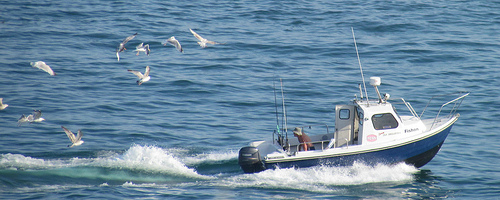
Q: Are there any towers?
A: No, there are no towers.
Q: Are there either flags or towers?
A: No, there are no towers or flags.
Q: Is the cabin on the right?
A: Yes, the cabin is on the right of the image.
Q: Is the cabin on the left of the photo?
A: No, the cabin is on the right of the image.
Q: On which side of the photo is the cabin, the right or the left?
A: The cabin is on the right of the image.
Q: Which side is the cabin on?
A: The cabin is on the right of the image.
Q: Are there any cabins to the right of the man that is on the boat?
A: Yes, there is a cabin to the right of the man.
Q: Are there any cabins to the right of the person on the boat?
A: Yes, there is a cabin to the right of the man.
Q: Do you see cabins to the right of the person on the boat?
A: Yes, there is a cabin to the right of the man.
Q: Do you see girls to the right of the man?
A: No, there is a cabin to the right of the man.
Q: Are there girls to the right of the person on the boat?
A: No, there is a cabin to the right of the man.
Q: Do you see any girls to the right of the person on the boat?
A: No, there is a cabin to the right of the man.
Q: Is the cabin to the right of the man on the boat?
A: Yes, the cabin is to the right of the man.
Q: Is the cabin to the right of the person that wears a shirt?
A: Yes, the cabin is to the right of the man.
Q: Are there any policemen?
A: No, there are no policemen.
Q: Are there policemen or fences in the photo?
A: No, there are no policemen or fences.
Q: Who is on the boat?
A: The man is on the boat.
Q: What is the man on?
A: The man is on the boat.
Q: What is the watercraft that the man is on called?
A: The watercraft is a boat.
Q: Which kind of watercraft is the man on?
A: The man is on the boat.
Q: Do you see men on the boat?
A: Yes, there is a man on the boat.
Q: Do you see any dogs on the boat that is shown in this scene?
A: No, there is a man on the boat.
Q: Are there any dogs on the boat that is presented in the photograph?
A: No, there is a man on the boat.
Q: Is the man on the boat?
A: Yes, the man is on the boat.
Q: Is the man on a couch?
A: No, the man is on the boat.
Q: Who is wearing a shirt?
A: The man is wearing a shirt.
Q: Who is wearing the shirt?
A: The man is wearing a shirt.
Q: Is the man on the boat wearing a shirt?
A: Yes, the man is wearing a shirt.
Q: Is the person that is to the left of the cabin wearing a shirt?
A: Yes, the man is wearing a shirt.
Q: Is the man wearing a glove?
A: No, the man is wearing a shirt.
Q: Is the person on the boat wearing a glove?
A: No, the man is wearing a shirt.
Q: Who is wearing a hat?
A: The man is wearing a hat.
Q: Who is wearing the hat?
A: The man is wearing a hat.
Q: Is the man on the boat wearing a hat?
A: Yes, the man is wearing a hat.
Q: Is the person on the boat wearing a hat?
A: Yes, the man is wearing a hat.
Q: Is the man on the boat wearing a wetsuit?
A: No, the man is wearing a hat.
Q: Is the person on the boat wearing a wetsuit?
A: No, the man is wearing a hat.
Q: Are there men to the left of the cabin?
A: Yes, there is a man to the left of the cabin.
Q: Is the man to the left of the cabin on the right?
A: Yes, the man is to the left of the cabin.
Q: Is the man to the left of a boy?
A: No, the man is to the left of the cabin.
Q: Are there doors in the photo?
A: Yes, there is a door.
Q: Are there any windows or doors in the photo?
A: Yes, there is a door.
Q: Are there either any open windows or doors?
A: Yes, there is an open door.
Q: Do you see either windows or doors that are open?
A: Yes, the door is open.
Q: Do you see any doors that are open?
A: Yes, there is an open door.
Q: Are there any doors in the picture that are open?
A: Yes, there is a door that is open.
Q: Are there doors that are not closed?
A: Yes, there is a open door.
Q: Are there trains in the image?
A: No, there are no trains.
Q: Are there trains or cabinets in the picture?
A: No, there are no trains or cabinets.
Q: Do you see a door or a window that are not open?
A: No, there is a door but it is open.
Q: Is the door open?
A: Yes, the door is open.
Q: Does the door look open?
A: Yes, the door is open.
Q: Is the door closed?
A: No, the door is open.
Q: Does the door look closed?
A: No, the door is open.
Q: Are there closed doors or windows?
A: No, there is a door but it is open.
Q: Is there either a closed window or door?
A: No, there is a door but it is open.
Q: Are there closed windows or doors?
A: No, there is a door but it is open.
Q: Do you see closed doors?
A: No, there is a door but it is open.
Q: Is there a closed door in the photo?
A: No, there is a door but it is open.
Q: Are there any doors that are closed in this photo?
A: No, there is a door but it is open.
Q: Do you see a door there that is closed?
A: No, there is a door but it is open.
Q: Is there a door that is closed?
A: No, there is a door but it is open.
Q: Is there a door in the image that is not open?
A: No, there is a door but it is open.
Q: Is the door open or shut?
A: The door is open.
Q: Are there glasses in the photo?
A: No, there are no glasses.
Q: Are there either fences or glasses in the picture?
A: No, there are no glasses or fences.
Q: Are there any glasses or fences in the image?
A: No, there are no glasses or fences.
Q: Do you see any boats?
A: Yes, there is a boat.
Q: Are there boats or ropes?
A: Yes, there is a boat.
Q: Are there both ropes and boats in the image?
A: No, there is a boat but no ropes.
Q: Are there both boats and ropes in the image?
A: No, there is a boat but no ropes.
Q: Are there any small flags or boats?
A: Yes, there is a small boat.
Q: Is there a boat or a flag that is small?
A: Yes, the boat is small.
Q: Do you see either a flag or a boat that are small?
A: Yes, the boat is small.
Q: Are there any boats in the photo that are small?
A: Yes, there is a small boat.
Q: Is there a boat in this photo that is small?
A: Yes, there is a small boat.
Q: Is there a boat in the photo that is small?
A: Yes, there is a boat that is small.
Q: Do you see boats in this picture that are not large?
A: Yes, there is a small boat.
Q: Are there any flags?
A: No, there are no flags.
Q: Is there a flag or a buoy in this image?
A: No, there are no flags or buoys.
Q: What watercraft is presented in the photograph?
A: The watercraft is a boat.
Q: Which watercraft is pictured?
A: The watercraft is a boat.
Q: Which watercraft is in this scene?
A: The watercraft is a boat.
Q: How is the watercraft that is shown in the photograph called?
A: The watercraft is a boat.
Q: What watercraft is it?
A: The watercraft is a boat.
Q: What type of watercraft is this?
A: This is a boat.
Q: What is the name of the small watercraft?
A: The watercraft is a boat.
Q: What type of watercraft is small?
A: The watercraft is a boat.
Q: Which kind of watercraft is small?
A: The watercraft is a boat.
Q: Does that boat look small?
A: Yes, the boat is small.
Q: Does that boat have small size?
A: Yes, the boat is small.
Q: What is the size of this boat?
A: The boat is small.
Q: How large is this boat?
A: The boat is small.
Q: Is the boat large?
A: No, the boat is small.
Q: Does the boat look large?
A: No, the boat is small.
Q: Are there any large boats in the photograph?
A: No, there is a boat but it is small.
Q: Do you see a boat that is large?
A: No, there is a boat but it is small.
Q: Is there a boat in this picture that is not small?
A: No, there is a boat but it is small.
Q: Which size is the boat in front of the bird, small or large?
A: The boat is small.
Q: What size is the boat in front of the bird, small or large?
A: The boat is small.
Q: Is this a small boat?
A: Yes, this is a small boat.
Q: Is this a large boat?
A: No, this is a small boat.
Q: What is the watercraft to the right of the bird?
A: The watercraft is a boat.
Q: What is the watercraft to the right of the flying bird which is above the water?
A: The watercraft is a boat.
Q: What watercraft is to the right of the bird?
A: The watercraft is a boat.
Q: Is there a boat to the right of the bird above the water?
A: Yes, there is a boat to the right of the bird.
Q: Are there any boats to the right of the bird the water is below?
A: Yes, there is a boat to the right of the bird.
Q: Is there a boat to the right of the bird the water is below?
A: Yes, there is a boat to the right of the bird.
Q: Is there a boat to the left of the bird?
A: No, the boat is to the right of the bird.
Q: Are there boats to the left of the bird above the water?
A: No, the boat is to the right of the bird.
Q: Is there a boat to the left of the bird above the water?
A: No, the boat is to the right of the bird.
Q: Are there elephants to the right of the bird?
A: No, there is a boat to the right of the bird.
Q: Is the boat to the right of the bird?
A: Yes, the boat is to the right of the bird.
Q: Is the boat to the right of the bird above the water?
A: Yes, the boat is to the right of the bird.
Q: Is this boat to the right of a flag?
A: No, the boat is to the right of the bird.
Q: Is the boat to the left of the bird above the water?
A: No, the boat is to the right of the bird.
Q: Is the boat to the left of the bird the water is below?
A: No, the boat is to the right of the bird.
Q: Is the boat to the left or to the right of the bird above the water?
A: The boat is to the right of the bird.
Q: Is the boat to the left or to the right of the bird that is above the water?
A: The boat is to the right of the bird.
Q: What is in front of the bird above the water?
A: The boat is in front of the bird.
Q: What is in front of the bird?
A: The boat is in front of the bird.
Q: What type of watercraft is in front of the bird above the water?
A: The watercraft is a boat.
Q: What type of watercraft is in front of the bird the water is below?
A: The watercraft is a boat.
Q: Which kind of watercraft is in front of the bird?
A: The watercraft is a boat.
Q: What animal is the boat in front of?
A: The boat is in front of the bird.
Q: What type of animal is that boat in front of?
A: The boat is in front of the bird.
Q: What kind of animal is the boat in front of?
A: The boat is in front of the bird.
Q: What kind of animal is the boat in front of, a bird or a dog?
A: The boat is in front of a bird.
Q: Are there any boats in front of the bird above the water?
A: Yes, there is a boat in front of the bird.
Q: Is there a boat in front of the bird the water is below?
A: Yes, there is a boat in front of the bird.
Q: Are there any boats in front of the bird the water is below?
A: Yes, there is a boat in front of the bird.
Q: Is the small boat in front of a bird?
A: Yes, the boat is in front of a bird.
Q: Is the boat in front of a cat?
A: No, the boat is in front of a bird.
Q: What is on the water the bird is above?
A: The boat is on the water.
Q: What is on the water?
A: The boat is on the water.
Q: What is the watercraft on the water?
A: The watercraft is a boat.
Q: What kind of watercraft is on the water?
A: The watercraft is a boat.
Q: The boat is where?
A: The boat is on the water.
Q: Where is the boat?
A: The boat is on the water.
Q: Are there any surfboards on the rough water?
A: No, there is a boat on the water.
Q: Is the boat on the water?
A: Yes, the boat is on the water.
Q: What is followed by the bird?
A: The boat is followed by the bird.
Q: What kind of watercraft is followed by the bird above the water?
A: The watercraft is a boat.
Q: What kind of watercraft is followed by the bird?
A: The watercraft is a boat.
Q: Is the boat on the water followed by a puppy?
A: No, the boat is followed by the bird.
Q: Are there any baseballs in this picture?
A: No, there are no baseballs.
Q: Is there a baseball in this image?
A: No, there are no baseballs.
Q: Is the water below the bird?
A: Yes, the water is below the bird.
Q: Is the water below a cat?
A: No, the water is below the bird.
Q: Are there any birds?
A: Yes, there is a bird.